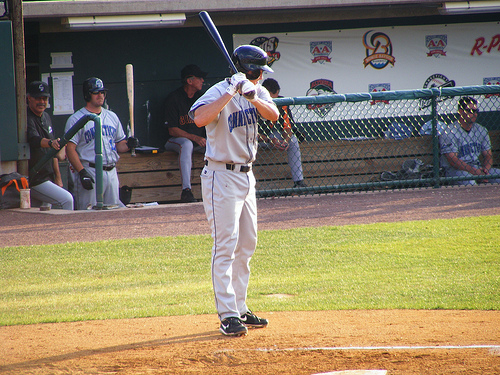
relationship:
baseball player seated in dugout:
[437, 92, 497, 181] [31, 92, 498, 202]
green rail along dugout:
[28, 114, 106, 215] [50, 114, 490, 188]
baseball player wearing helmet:
[186, 43, 280, 338] [228, 45, 273, 72]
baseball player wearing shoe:
[186, 43, 280, 338] [218, 317, 248, 337]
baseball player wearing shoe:
[186, 43, 280, 338] [241, 312, 269, 328]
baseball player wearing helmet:
[65, 76, 141, 210] [82, 78, 109, 98]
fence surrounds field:
[316, 93, 388, 183] [302, 190, 451, 240]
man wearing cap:
[24, 81, 74, 211] [27, 79, 50, 99]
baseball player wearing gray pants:
[186, 43, 280, 338] [198, 158, 256, 312]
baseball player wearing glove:
[186, 43, 280, 338] [240, 80, 258, 100]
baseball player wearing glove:
[186, 43, 280, 338] [225, 68, 247, 95]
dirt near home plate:
[337, 324, 411, 353] [309, 362, 383, 375]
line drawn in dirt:
[322, 345, 499, 350] [357, 320, 436, 349]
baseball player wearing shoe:
[186, 43, 280, 338] [238, 306, 268, 329]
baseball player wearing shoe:
[186, 43, 280, 338] [215, 311, 251, 338]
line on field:
[224, 342, 499, 358] [11, 172, 497, 372]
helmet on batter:
[235, 43, 272, 71] [144, 4, 340, 313]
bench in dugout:
[123, 131, 433, 190] [7, 3, 498, 223]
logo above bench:
[356, 26, 398, 75] [308, 135, 433, 174]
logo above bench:
[303, 33, 338, 73] [308, 135, 433, 174]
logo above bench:
[311, 77, 338, 119] [308, 135, 433, 174]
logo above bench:
[420, 26, 456, 61] [308, 135, 433, 174]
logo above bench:
[468, 31, 498, 62] [308, 135, 433, 174]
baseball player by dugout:
[65, 76, 141, 210] [7, 3, 498, 223]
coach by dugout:
[14, 71, 87, 212] [7, 3, 498, 223]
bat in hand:
[110, 65, 158, 137] [120, 119, 134, 148]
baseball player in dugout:
[65, 76, 141, 210] [59, 51, 463, 190]